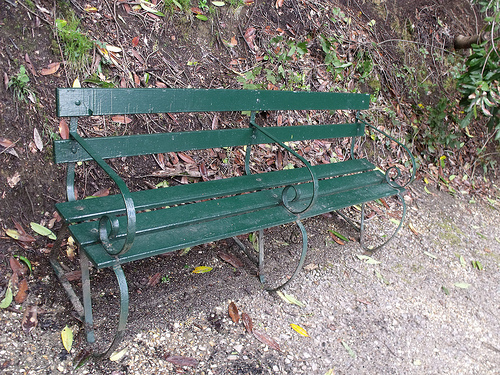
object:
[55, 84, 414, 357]
bench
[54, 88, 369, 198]
back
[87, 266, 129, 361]
support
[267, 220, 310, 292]
support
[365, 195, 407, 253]
support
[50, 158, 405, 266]
seat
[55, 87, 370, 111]
rail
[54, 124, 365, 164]
rail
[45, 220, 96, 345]
support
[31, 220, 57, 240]
leaf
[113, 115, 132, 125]
leaf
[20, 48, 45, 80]
leaf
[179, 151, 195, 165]
leaf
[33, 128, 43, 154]
leaf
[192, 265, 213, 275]
leaf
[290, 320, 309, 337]
leaf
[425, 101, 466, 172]
plant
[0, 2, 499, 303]
dirt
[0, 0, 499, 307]
hill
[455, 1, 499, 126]
branch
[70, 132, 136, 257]
armrest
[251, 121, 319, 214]
armrest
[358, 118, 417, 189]
armrest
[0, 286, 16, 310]
leaf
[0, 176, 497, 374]
ground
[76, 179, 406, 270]
slat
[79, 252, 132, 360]
leg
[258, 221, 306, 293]
leg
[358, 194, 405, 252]
leg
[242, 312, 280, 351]
leaf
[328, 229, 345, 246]
leaf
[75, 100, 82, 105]
bolt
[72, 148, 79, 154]
bolt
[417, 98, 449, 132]
grass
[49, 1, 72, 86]
twig